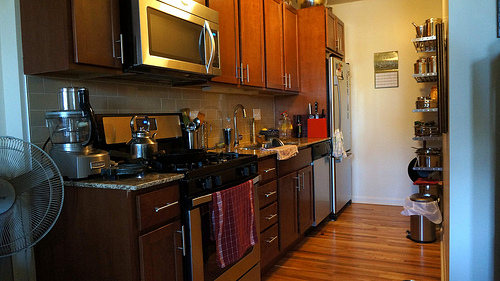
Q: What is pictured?
A: Someones kitchen.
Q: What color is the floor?
A: Brown.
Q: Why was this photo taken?
A: To show the kitchen.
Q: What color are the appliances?
A: SIlver.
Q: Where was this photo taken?
A: At someones house.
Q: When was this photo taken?
A: During the day.